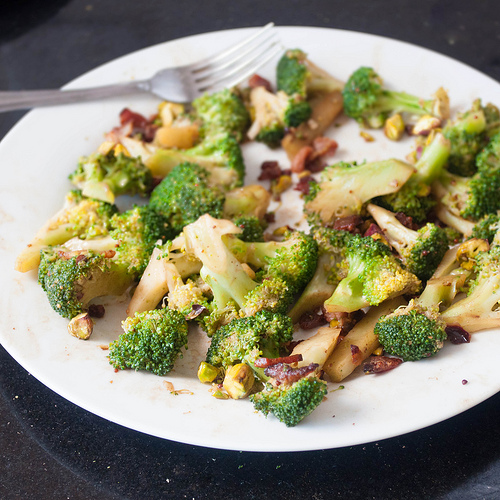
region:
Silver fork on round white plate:
[0, 15, 280, 121]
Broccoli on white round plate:
[342, 66, 429, 117]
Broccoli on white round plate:
[103, 291, 193, 374]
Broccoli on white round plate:
[369, 276, 451, 358]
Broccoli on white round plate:
[37, 241, 128, 315]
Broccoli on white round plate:
[12, 189, 117, 274]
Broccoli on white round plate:
[145, 165, 270, 229]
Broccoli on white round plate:
[297, 155, 414, 230]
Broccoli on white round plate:
[129, 132, 248, 173]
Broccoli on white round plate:
[248, 81, 304, 144]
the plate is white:
[104, 319, 210, 389]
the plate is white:
[146, 389, 310, 496]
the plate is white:
[155, 419, 253, 488]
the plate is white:
[85, 355, 207, 473]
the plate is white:
[149, 352, 251, 453]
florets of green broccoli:
[153, 202, 320, 363]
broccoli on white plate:
[69, 120, 498, 425]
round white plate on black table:
[57, 50, 499, 410]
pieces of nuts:
[176, 350, 253, 401]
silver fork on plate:
[1, 29, 291, 133]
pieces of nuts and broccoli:
[171, 113, 377, 235]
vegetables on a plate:
[105, 84, 427, 357]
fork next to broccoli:
[127, 33, 331, 169]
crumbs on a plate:
[165, 377, 200, 419]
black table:
[29, 417, 156, 494]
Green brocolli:
[114, 320, 196, 369]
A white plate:
[81, 361, 193, 436]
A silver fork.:
[62, 63, 242, 100]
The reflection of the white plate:
[32, 420, 127, 495]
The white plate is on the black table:
[15, 436, 138, 489]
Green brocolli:
[346, 68, 375, 113]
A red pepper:
[262, 350, 311, 382]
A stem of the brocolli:
[188, 213, 238, 267]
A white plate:
[19, 126, 77, 164]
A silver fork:
[63, 57, 240, 89]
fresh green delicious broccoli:
[124, 317, 174, 371]